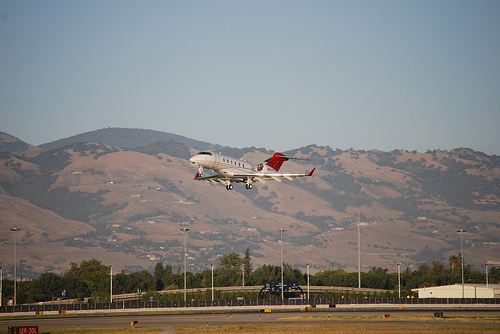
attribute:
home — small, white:
[409, 275, 498, 307]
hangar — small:
[406, 271, 498, 311]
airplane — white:
[187, 150, 315, 191]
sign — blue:
[239, 266, 321, 307]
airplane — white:
[158, 114, 389, 217]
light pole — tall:
[271, 220, 289, 310]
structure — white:
[406, 279, 498, 306]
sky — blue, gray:
[5, 7, 498, 152]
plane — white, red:
[188, 148, 318, 193]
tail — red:
[260, 150, 295, 172]